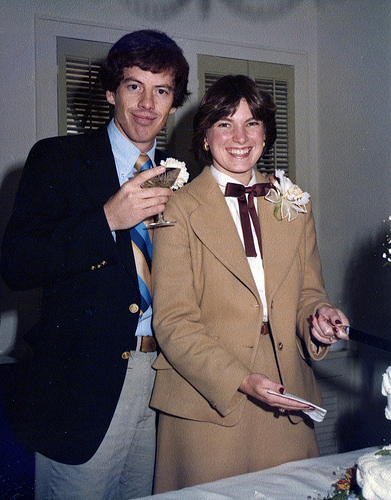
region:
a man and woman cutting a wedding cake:
[13, 27, 390, 482]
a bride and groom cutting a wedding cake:
[93, 28, 387, 484]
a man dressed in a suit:
[6, 25, 196, 489]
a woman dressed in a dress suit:
[165, 72, 357, 468]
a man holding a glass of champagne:
[15, 19, 192, 237]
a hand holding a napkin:
[244, 369, 336, 429]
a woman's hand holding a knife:
[308, 297, 388, 365]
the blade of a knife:
[346, 320, 389, 355]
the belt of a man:
[122, 328, 165, 359]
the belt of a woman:
[251, 316, 274, 337]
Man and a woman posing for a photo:
[2, 29, 351, 497]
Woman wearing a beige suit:
[148, 72, 354, 494]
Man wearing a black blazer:
[2, 26, 188, 498]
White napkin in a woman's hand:
[264, 388, 327, 424]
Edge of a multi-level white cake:
[353, 359, 390, 498]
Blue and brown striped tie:
[129, 151, 157, 313]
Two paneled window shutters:
[52, 33, 298, 188]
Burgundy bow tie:
[223, 181, 275, 259]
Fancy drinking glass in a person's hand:
[130, 163, 180, 228]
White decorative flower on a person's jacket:
[264, 168, 309, 223]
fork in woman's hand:
[310, 304, 354, 344]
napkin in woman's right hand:
[248, 372, 327, 422]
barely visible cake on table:
[140, 364, 390, 499]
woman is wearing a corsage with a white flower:
[262, 168, 311, 219]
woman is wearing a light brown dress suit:
[151, 165, 331, 488]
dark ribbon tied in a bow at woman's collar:
[223, 181, 267, 256]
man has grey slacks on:
[33, 336, 155, 499]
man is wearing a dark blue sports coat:
[4, 129, 202, 464]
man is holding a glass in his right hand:
[113, 165, 180, 228]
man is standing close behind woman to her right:
[2, 29, 348, 498]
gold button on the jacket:
[127, 301, 140, 316]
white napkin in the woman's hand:
[265, 385, 328, 422]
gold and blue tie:
[131, 153, 157, 319]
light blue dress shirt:
[105, 116, 158, 337]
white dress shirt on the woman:
[208, 164, 270, 320]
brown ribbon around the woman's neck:
[224, 181, 267, 258]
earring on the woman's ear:
[202, 138, 210, 151]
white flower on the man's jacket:
[159, 156, 191, 193]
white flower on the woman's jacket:
[263, 166, 310, 221]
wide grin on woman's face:
[219, 146, 262, 161]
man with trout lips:
[121, 108, 166, 133]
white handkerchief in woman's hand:
[256, 380, 334, 419]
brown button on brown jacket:
[205, 395, 221, 410]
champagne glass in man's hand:
[135, 164, 187, 233]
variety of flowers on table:
[321, 466, 348, 491]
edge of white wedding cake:
[347, 456, 380, 480]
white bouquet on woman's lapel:
[263, 175, 318, 212]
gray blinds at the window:
[270, 60, 302, 101]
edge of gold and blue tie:
[129, 150, 153, 174]